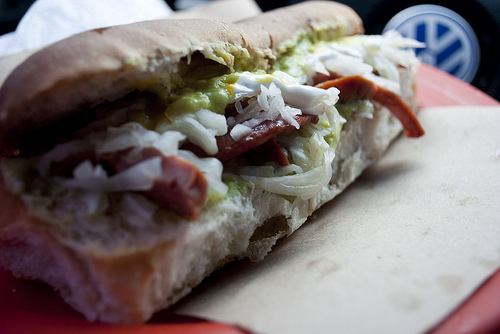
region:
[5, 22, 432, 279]
a sandwich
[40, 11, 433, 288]
a sandwich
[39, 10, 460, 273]
a sandwich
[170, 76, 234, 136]
the sauce is green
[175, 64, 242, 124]
the sauce is green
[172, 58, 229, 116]
the sauce is green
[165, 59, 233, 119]
the sauce is green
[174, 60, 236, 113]
the sauce is green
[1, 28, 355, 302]
sandwich on the plate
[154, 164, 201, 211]
meat on the sandwich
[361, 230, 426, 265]
napkin on the plate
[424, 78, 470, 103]
the plate is red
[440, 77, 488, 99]
the plate is glass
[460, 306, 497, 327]
the plate is round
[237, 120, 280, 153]
this is a beef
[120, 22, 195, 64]
this is a ban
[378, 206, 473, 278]
the mat is white in color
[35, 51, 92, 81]
this is the bread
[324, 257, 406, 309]
the serviette is brown in colour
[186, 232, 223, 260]
the bread is white in colour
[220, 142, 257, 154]
this is the bacon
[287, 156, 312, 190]
this is the onion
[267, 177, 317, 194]
the onion is white in colour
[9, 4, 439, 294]
A fresh hoagie sandwich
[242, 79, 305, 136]
Diced onions on a sandwich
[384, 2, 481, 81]
a Volkswagen sticker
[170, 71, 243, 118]
a spoonful of avocado sauce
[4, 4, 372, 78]
the top part of a hoagie sandwich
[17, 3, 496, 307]
A hoagie sandwich on a napkin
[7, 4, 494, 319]
Hoagie sandwich on an orange plate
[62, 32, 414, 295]
this is a lunch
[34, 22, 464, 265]
this is a sandwich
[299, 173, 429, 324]
the paper is white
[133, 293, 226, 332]
the tray is plastic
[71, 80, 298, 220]
the sandwich has veggies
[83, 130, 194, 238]
the veggies are white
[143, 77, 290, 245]
the veggies are red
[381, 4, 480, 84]
vw logo on steering wheel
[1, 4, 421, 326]
food is on plate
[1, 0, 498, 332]
napkin is under food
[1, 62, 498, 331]
plate is under napkin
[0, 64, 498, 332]
plate is red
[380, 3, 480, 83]
logo is silver and blue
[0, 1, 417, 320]
food is on a bun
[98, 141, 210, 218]
piece of meat in on bun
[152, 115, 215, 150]
piece of grated cheese is covered with sauce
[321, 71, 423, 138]
piece of meat is hanging off bun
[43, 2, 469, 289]
a bread cut in half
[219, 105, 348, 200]
meat on the sandwich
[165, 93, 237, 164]
cheese on the sandwich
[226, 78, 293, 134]
cheese on the sandwich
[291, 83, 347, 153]
cheese on the sandwich